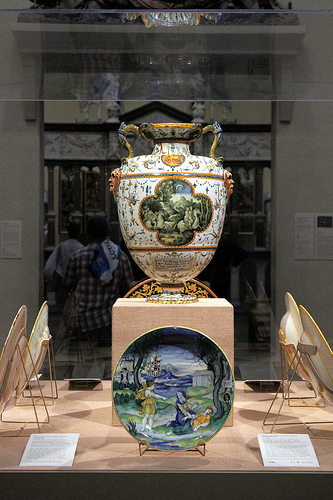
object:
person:
[172, 390, 195, 427]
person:
[166, 406, 212, 436]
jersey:
[89, 239, 121, 285]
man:
[45, 221, 89, 308]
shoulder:
[103, 241, 131, 266]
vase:
[108, 102, 239, 308]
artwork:
[111, 324, 236, 457]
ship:
[145, 354, 162, 377]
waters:
[146, 372, 190, 391]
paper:
[19, 432, 79, 466]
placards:
[16, 424, 78, 467]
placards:
[256, 426, 319, 470]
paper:
[255, 433, 322, 467]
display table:
[0, 377, 332, 468]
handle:
[200, 120, 226, 166]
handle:
[114, 114, 140, 158]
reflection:
[56, 217, 135, 340]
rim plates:
[296, 303, 332, 395]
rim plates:
[277, 288, 306, 387]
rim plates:
[14, 299, 52, 395]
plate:
[296, 303, 332, 380]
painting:
[119, 339, 223, 445]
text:
[27, 436, 69, 463]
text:
[263, 433, 311, 458]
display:
[1, 97, 323, 472]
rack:
[136, 437, 206, 456]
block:
[112, 295, 236, 428]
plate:
[110, 323, 235, 455]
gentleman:
[62, 216, 143, 357]